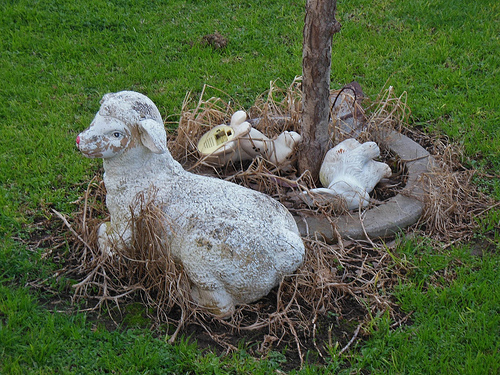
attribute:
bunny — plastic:
[198, 110, 300, 162]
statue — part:
[74, 86, 399, 320]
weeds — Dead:
[137, 213, 193, 327]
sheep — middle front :
[43, 82, 293, 303]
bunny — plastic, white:
[299, 139, 380, 204]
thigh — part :
[183, 230, 274, 297]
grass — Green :
[340, 7, 498, 93]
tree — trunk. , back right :
[293, 1, 346, 174]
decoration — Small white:
[195, 110, 302, 172]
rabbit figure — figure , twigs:
[299, 136, 390, 208]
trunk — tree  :
[299, 0, 341, 186]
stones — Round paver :
[188, 82, 440, 242]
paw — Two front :
[359, 139, 384, 159]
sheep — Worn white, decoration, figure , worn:
[70, 89, 307, 318]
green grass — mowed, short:
[92, 29, 446, 66]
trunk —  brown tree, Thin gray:
[296, 1, 342, 183]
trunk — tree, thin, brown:
[290, 0, 341, 182]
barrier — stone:
[295, 116, 441, 245]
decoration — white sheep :
[77, 89, 304, 319]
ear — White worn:
[290, 170, 362, 232]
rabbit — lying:
[287, 122, 441, 267]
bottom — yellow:
[190, 122, 235, 154]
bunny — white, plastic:
[308, 136, 391, 209]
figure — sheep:
[73, 79, 333, 319]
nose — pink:
[70, 134, 90, 152]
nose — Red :
[74, 126, 104, 154]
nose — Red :
[73, 138, 90, 148]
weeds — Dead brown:
[317, 252, 359, 316]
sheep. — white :
[82, 57, 294, 312]